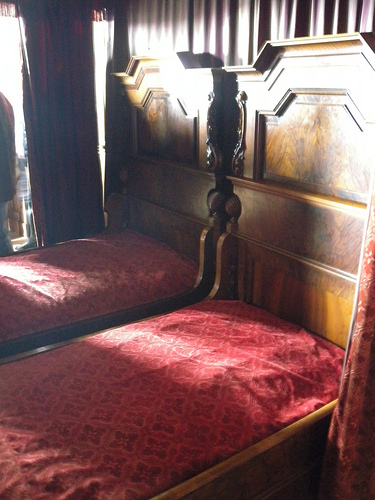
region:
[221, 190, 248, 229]
a brown wooden bed post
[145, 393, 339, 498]
the rail of the bed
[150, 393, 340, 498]
the side of the bed frame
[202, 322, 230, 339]
a diamond pattern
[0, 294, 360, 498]
a red bed spread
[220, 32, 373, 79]
the top of a head board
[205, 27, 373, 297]
a brown wooden head board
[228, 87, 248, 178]
a decoration on the head board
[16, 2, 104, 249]
a dark curtain on the window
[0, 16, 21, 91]
a gray sky outside the window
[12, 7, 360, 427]
Two vintage beds with wooden head boards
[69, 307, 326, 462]
Red sheet on bed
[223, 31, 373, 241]
Brown wooden head board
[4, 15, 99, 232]
Red and Brown Window shades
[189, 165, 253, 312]
Wooden finials on bed head board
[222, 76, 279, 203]
Floral carving on bed head board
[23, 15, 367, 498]
Two twin beds with wooden head boards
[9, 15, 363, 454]
Two beds along side each other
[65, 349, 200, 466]
Twin bed sheet with floral pattern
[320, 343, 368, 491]
Red colored drape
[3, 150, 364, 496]
two beds with red sheets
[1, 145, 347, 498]
two beds with brown wooden headboards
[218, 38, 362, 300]
wooden headboard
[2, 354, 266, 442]
rows of red pattern on sheet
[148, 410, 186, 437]
red design on sheet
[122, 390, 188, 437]
four red floral designs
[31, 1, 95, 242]
red curtain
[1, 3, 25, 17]
red fringes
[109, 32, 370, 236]
double wooden headboards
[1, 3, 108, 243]
red curtain partially covering the window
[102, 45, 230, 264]
a wooden head board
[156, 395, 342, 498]
the wooden side of a bed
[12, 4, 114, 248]
dark curtains on the window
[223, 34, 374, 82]
the top of the head board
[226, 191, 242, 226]
a bed post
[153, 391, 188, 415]
a diamond pattern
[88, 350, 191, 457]
red sheet on bed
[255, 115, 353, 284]
brown wooden headboard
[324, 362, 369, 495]
Red drapes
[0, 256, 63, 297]
sunlight on red bed sheet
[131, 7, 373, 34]
brown drapes behind bed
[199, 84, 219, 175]
design on bed headboard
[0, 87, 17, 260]
a person in red shirt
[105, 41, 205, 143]
sunlight reflecting off headboard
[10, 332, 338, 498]
a bed with a red top sheet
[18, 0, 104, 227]
a dark red drape